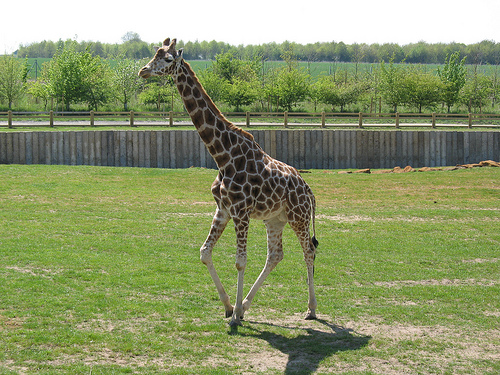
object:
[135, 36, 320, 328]
giraffe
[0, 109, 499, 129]
fence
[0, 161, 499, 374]
grass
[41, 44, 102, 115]
tree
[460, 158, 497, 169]
rocks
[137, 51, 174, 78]
face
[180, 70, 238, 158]
neck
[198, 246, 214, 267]
knee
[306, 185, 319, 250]
tail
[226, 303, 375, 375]
shadow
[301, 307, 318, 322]
hoof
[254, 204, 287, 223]
stomach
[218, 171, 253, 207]
chest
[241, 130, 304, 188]
back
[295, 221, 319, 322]
leg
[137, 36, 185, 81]
head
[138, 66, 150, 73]
nose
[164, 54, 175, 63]
eye